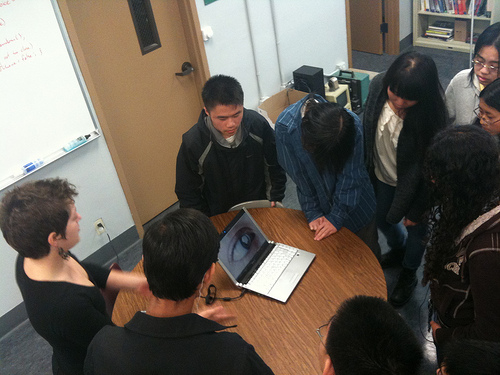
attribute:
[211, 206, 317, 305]
laptop — silver, open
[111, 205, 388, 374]
table — small, round, circular, wooden, brown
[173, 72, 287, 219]
man — standing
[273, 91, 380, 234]
shirt — blue, white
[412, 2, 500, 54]
book case — small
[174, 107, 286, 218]
jacket — gray, black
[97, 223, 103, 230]
plug — plugged in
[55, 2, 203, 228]
door — tan, closed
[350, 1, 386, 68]
door — open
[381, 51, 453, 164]
hair — black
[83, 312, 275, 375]
shirt — black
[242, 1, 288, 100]
molding — gray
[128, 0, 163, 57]
window — small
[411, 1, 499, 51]
shelf — distant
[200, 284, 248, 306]
cord — black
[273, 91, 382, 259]
boy — leaning